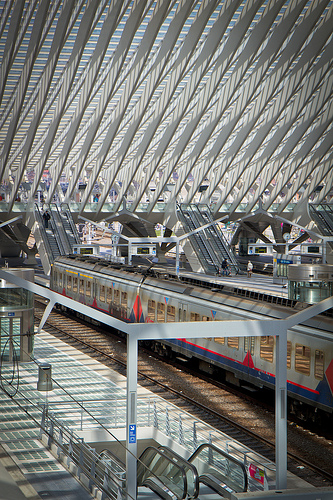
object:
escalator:
[35, 205, 60, 262]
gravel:
[57, 314, 75, 326]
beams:
[7, 5, 328, 218]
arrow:
[130, 426, 134, 431]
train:
[49, 253, 330, 408]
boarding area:
[235, 277, 331, 304]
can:
[38, 361, 53, 392]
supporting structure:
[123, 319, 141, 500]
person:
[43, 209, 50, 228]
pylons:
[247, 464, 269, 494]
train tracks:
[166, 361, 210, 383]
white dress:
[247, 263, 253, 271]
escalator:
[178, 210, 215, 275]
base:
[216, 268, 222, 277]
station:
[2, 5, 329, 499]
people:
[247, 259, 253, 278]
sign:
[129, 423, 136, 443]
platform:
[16, 380, 191, 447]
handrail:
[63, 428, 118, 496]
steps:
[47, 236, 55, 239]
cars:
[136, 279, 248, 385]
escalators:
[54, 201, 81, 252]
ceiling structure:
[130, 105, 186, 207]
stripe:
[82, 305, 103, 322]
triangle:
[249, 350, 254, 368]